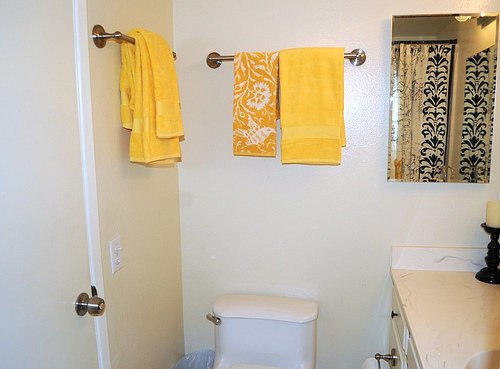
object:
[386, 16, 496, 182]
reflection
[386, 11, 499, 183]
mirror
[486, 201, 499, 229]
candle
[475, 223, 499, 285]
candle holder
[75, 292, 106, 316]
doorknob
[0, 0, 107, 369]
door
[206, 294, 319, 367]
tank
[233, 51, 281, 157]
towel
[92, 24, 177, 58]
rack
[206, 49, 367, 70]
rack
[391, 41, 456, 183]
curtain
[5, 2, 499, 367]
bathroom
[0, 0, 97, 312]
white wall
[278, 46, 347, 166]
towel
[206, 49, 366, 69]
metal bar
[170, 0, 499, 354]
wall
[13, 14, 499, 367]
picture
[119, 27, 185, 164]
handtowel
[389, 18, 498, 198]
shower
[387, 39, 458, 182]
cupboard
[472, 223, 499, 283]
holder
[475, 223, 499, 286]
stand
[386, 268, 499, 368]
counter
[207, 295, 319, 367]
toliet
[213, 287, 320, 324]
cover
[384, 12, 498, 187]
medicine chest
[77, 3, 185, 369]
wall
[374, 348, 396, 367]
handle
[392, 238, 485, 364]
sink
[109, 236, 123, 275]
light switches